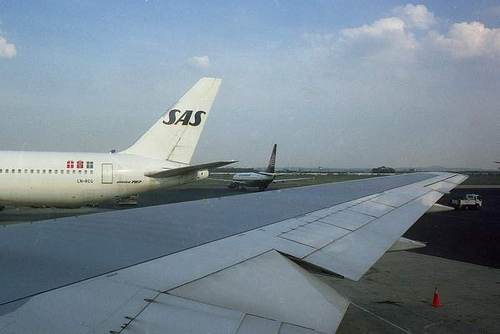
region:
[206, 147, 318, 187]
airplane on the tarmac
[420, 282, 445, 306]
small orange traffic cone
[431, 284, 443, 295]
white strip on the orange traffic cone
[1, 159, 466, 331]
long, gray airplane wing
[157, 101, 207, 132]
black writing on the plane's tail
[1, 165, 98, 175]
row of small windows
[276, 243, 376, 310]
cut in the wing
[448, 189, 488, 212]
white truck driving on the tarmac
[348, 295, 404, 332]
white line painted on the ground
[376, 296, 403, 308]
dark spot on the concrete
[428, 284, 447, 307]
orange and white traffic cone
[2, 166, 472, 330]
grey metallic air plane wing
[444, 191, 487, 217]
air port transportation vehicle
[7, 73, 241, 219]
big white jet airliner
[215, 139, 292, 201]
air plane parked at the air port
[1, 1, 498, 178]
blue sky with a few clouds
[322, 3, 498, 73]
puffy white clouds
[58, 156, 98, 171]
three flags on the side of a plane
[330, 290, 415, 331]
painted white lines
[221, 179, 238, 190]
left side jet engine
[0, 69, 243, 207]
part of a white plane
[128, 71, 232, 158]
vertical stabilizer of a plane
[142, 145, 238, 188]
side horizontal stabilizer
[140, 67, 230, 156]
the word SAS on the vertical stabilizer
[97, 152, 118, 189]
back door of a plane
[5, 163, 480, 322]
wing of a plane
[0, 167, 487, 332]
wing is color gray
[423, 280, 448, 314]
an orange cone on the landing lane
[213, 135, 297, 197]
a plane on an airport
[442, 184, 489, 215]
a white truck in an airport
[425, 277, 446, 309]
orange and white cone on tarmac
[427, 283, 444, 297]
white stripe at top of orange traffic cone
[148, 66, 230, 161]
tail of white plane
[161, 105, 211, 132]
three letter word on tail of plane in black lettering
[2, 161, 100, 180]
row of windows on side of plane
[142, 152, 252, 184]
back wing of airplane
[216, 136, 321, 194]
grounded airplane on tarmac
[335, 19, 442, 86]
white cloud in blue sky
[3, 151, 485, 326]
close up of metal wing of airplane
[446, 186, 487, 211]
white truck driving on tarmac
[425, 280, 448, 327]
orange cone on the runway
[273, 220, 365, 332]
gap in air plane flap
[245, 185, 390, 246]
rivets holding air plane together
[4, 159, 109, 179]
windows on the airplane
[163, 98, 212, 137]
logo on airplane tail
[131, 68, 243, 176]
airplane tail against sky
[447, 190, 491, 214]
truck on the runway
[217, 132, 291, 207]
airplane in the background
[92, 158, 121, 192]
door on the airplane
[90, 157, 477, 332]
wing of the airplane